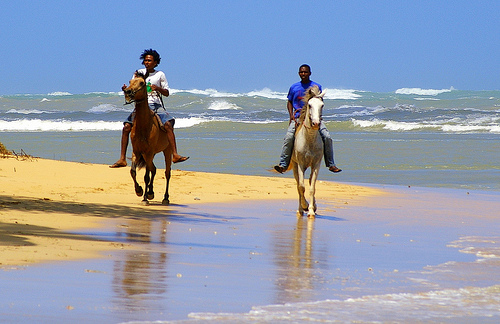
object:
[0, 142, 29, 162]
vegetation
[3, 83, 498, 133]
waves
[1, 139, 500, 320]
beach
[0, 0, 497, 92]
sky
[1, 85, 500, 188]
ocean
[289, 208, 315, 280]
reflection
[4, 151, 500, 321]
sand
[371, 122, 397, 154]
ground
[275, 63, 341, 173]
man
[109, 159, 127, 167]
foot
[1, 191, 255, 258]
shadows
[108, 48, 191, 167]
boy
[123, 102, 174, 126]
jeans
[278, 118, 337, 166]
jeans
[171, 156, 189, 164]
foot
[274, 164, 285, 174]
foot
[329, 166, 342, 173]
foot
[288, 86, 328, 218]
horse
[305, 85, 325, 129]
head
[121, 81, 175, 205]
horse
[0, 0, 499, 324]
photograph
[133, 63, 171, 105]
shirt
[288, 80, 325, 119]
shirt